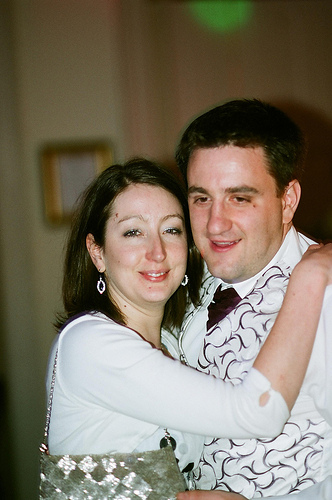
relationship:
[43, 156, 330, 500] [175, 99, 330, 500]
woman huge man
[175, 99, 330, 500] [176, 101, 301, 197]
man has hair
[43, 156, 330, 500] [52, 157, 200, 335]
woman has hair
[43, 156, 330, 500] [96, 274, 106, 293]
woman has ear ring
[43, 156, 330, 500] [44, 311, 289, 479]
woman has shirt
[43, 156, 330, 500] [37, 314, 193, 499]
woman has purse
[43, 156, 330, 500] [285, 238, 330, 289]
woman has hand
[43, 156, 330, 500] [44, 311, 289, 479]
woman has blouse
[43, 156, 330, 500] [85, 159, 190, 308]
woman has head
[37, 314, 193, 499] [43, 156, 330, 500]
purse near woman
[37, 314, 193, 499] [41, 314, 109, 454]
purse has strap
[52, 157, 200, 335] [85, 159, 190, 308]
hair on head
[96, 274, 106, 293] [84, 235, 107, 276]
ear ring on ear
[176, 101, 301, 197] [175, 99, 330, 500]
hair on man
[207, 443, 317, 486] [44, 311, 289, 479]
pattern on shirt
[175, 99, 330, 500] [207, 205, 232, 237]
man has nose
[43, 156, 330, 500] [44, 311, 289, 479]
woman wears shirt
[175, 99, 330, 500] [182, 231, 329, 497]
man wears shirt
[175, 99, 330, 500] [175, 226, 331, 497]
man wears vest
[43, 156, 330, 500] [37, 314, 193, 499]
woman wears purse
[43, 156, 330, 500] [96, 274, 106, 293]
woman wears ear ring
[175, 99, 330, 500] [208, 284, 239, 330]
man wears tie